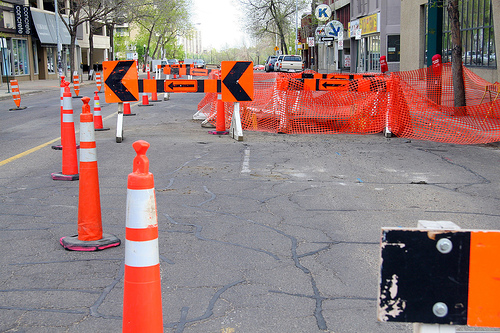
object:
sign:
[377, 219, 500, 332]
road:
[0, 69, 500, 333]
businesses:
[0, 0, 155, 83]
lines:
[245, 189, 356, 331]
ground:
[401, 139, 438, 178]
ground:
[391, 144, 428, 196]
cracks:
[141, 145, 329, 324]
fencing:
[197, 61, 500, 145]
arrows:
[104, 60, 346, 102]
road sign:
[50, 72, 162, 333]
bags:
[380, 55, 389, 72]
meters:
[379, 54, 442, 108]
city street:
[0, 61, 499, 333]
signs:
[314, 4, 332, 22]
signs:
[324, 20, 344, 40]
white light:
[102, 59, 255, 103]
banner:
[375, 226, 500, 328]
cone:
[121, 140, 163, 333]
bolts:
[432, 237, 452, 318]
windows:
[434, 0, 497, 68]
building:
[399, 0, 500, 84]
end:
[377, 227, 471, 326]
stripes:
[125, 187, 160, 268]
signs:
[102, 60, 386, 104]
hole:
[409, 181, 428, 185]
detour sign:
[102, 60, 140, 104]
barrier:
[375, 220, 500, 333]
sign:
[71, 60, 253, 135]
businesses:
[296, 0, 500, 93]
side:
[0, 0, 77, 45]